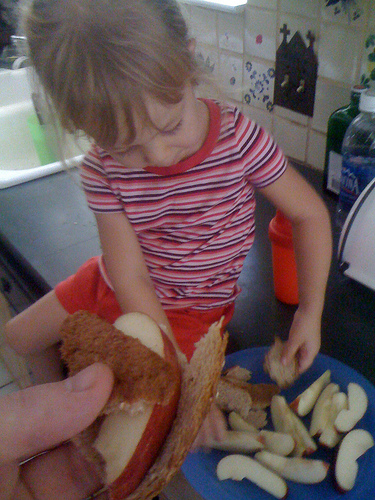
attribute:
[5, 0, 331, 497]
toddler — blonde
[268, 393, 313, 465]
slice — apple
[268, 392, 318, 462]
apple — sliced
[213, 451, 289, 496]
slice — apple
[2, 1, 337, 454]
toddler — eating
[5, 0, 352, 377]
girl — little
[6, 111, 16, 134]
white — is double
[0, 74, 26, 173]
sink — is white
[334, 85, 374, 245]
bottle — clear, plastic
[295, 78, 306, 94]
light switch — cream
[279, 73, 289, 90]
light switch — cream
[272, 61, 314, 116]
swich — dark brown, light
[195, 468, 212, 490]
plate — round, blue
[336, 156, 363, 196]
label — blue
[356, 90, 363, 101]
lid — white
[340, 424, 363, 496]
slice — apple